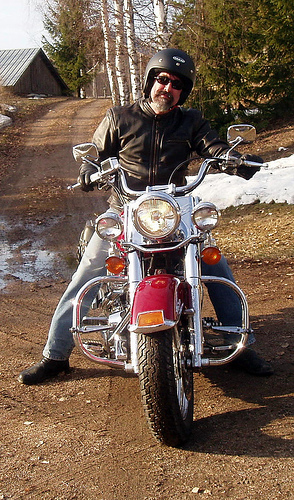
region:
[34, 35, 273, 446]
The man is on a motorcycle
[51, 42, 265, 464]
The man is riding his motorcycle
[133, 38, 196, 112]
The man is wearing a helmet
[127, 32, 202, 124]
The man is wearing sunglasses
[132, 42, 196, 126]
The man has hair growing on his face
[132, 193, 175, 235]
Headlight of a new motorcycle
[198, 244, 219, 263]
Turn signal of a motorcycle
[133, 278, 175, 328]
Front fender of a motorcycle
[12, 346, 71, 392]
A boot is on someone's foot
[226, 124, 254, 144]
Rear view mirror of a motorcycle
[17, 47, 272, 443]
a man on a motorcycle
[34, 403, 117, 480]
dirt and gravel road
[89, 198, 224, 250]
head lights on a bike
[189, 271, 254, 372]
foot rest on a bike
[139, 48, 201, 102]
mans head in a helmet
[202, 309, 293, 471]
shadow of a bike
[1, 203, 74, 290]
water hole on the road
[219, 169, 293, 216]
snow on the ground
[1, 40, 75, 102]
part of a barn roof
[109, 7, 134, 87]
white tree trunks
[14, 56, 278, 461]
man sitting on motorcycle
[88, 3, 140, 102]
birch trees behind the man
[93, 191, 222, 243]
headlights on the motorcycle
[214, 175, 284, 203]
white snow on the ground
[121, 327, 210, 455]
wheel on the motorcycle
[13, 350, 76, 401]
black boot on the man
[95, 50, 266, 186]
man wearing black leather jacket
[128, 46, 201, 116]
man wearing sunglasses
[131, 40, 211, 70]
black helmet that man is wearing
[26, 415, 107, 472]
tan dirt road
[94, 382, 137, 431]
tracks on the dirt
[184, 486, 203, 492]
small white stone on the dirt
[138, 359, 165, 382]
grooves in the black wheel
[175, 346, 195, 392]
silver rims in wheel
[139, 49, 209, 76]
large black helmet on rider's head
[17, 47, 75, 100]
large barn at back of rider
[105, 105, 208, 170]
man wearing shiny black jacket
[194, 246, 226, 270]
lights on front of bike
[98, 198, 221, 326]
silver frame on bike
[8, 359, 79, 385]
man wearing black shoes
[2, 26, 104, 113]
Rooftop to a house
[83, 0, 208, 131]
Birch wood trees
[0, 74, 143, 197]
Dirt Road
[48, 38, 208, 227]
Man sitting on motorcycle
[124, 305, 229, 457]
Blakc tires on motorcycle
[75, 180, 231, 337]
White and orange lights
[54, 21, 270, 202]
Man wearing a leather jacket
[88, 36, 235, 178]
Man wearing a helmet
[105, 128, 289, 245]
Patch of snow on the ground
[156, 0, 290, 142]
Pine trees in background